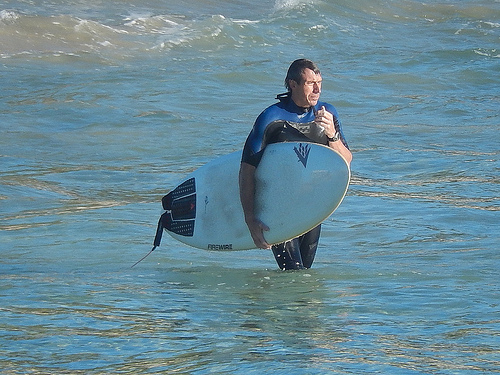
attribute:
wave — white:
[173, 8, 284, 53]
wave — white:
[63, 322, 194, 347]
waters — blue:
[1, 1, 499, 372]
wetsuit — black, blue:
[238, 100, 363, 282]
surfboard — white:
[147, 141, 356, 267]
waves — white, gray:
[125, 271, 426, 339]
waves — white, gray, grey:
[0, 0, 499, 373]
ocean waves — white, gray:
[0, 7, 261, 62]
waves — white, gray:
[4, 3, 496, 78]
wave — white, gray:
[2, 4, 135, 54]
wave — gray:
[118, 7, 195, 39]